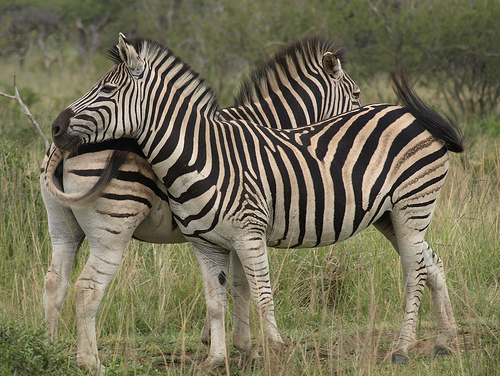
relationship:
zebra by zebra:
[51, 30, 470, 351] [33, 26, 376, 374]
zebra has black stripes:
[51, 30, 470, 351] [48, 32, 463, 345]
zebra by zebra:
[33, 26, 376, 374] [51, 30, 470, 351]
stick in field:
[1, 70, 54, 154] [15, 82, 494, 372]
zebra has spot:
[51, 30, 470, 351] [210, 264, 236, 304]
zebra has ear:
[51, 30, 470, 351] [114, 30, 142, 90]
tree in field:
[1, 0, 126, 131] [15, 82, 494, 372]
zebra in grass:
[51, 30, 470, 351] [15, 82, 494, 372]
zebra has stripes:
[51, 30, 470, 351] [48, 32, 463, 345]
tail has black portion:
[21, 140, 138, 212] [75, 143, 140, 206]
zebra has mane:
[51, 30, 470, 351] [114, 17, 218, 125]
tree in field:
[352, 1, 496, 123] [15, 82, 494, 372]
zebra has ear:
[33, 26, 376, 374] [311, 47, 341, 80]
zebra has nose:
[51, 30, 470, 351] [48, 120, 79, 158]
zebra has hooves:
[51, 30, 470, 351] [196, 339, 470, 370]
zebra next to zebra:
[51, 30, 470, 351] [33, 26, 376, 374]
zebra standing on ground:
[33, 26, 376, 374] [8, 265, 490, 373]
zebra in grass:
[33, 26, 376, 374] [15, 82, 494, 372]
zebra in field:
[33, 26, 376, 374] [15, 82, 494, 372]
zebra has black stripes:
[33, 26, 376, 374] [48, 32, 463, 345]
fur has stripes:
[51, 22, 454, 357] [48, 32, 463, 345]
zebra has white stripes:
[51, 30, 470, 351] [51, 22, 454, 357]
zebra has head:
[51, 30, 470, 351] [44, 35, 186, 170]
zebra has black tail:
[51, 30, 470, 351] [386, 52, 469, 180]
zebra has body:
[51, 30, 470, 351] [176, 88, 455, 275]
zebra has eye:
[33, 26, 376, 374] [350, 83, 362, 104]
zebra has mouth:
[51, 30, 470, 351] [54, 135, 79, 152]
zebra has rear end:
[33, 26, 376, 374] [20, 139, 148, 254]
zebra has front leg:
[51, 30, 470, 351] [189, 237, 236, 374]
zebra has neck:
[51, 30, 470, 351] [137, 65, 211, 197]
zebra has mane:
[33, 26, 376, 374] [219, 31, 352, 112]